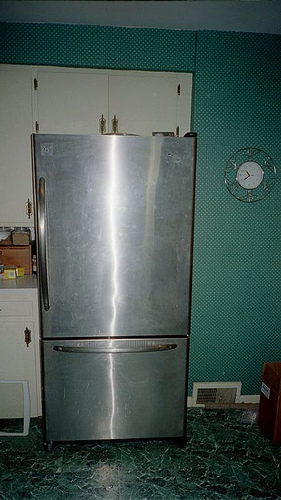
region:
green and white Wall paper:
[6, 23, 25, 42]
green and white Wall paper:
[199, 353, 220, 377]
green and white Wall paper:
[221, 351, 242, 378]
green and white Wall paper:
[242, 353, 258, 395]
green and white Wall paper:
[198, 319, 222, 344]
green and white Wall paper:
[217, 308, 241, 342]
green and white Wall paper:
[245, 309, 276, 341]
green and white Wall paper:
[204, 263, 249, 307]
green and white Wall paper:
[246, 255, 268, 307]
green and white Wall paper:
[205, 246, 251, 283]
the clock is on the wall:
[223, 141, 277, 210]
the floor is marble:
[103, 459, 252, 496]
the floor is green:
[17, 460, 126, 497]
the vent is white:
[193, 381, 240, 403]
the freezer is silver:
[41, 339, 191, 446]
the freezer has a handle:
[52, 336, 177, 361]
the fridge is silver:
[31, 133, 191, 334]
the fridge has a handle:
[29, 133, 195, 334]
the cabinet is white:
[5, 296, 38, 345]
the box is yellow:
[3, 265, 25, 279]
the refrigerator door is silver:
[27, 128, 187, 433]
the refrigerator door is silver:
[24, 113, 170, 291]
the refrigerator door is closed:
[27, 318, 226, 491]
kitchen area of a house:
[0, 0, 280, 499]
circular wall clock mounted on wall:
[222, 146, 280, 205]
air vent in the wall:
[190, 379, 243, 409]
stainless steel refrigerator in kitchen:
[29, 130, 198, 448]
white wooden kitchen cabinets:
[0, 62, 199, 419]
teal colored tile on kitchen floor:
[1, 401, 279, 498]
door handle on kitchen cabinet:
[22, 325, 33, 348]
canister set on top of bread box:
[0, 226, 32, 247]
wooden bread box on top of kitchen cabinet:
[0, 243, 32, 277]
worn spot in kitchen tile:
[89, 459, 134, 499]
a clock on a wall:
[221, 141, 279, 211]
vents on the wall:
[191, 375, 244, 413]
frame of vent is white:
[187, 376, 241, 407]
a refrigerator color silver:
[24, 120, 193, 455]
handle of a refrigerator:
[31, 173, 60, 317]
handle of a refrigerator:
[52, 343, 178, 355]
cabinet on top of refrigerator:
[28, 76, 188, 137]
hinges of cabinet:
[28, 72, 44, 135]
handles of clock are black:
[243, 165, 254, 180]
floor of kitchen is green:
[2, 438, 278, 498]